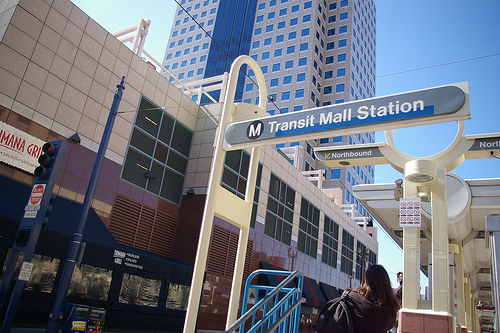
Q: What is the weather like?
A: It is clear.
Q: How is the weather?
A: It is clear.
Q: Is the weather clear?
A: Yes, it is clear.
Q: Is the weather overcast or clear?
A: It is clear.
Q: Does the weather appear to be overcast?
A: No, it is clear.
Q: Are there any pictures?
A: No, there are no pictures.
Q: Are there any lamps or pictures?
A: No, there are no pictures or lamps.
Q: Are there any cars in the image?
A: No, there are no cars.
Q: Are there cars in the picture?
A: No, there are no cars.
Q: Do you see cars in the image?
A: No, there are no cars.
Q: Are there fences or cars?
A: No, there are no cars or fences.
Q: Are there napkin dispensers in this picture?
A: No, there are no napkin dispensers.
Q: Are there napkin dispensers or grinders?
A: No, there are no napkin dispensers or grinders.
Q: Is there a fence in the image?
A: No, there are no fences.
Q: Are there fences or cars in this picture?
A: No, there are no fences or cars.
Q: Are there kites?
A: No, there are no kites.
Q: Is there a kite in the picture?
A: No, there are no kites.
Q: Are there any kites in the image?
A: No, there are no kites.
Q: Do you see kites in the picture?
A: No, there are no kites.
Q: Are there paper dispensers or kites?
A: No, there are no kites or paper dispensers.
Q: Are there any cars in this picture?
A: No, there are no cars.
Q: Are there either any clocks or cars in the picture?
A: No, there are no cars or clocks.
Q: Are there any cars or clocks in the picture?
A: No, there are no cars or clocks.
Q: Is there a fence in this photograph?
A: No, there are no fences.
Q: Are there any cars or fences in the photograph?
A: No, there are no fences or cars.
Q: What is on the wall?
A: The sign is on the wall.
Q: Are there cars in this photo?
A: No, there are no cars.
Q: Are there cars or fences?
A: No, there are no cars or fences.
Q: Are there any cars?
A: No, there are no cars.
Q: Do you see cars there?
A: No, there are no cars.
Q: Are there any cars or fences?
A: No, there are no cars or fences.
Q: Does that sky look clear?
A: Yes, the sky is clear.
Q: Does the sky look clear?
A: Yes, the sky is clear.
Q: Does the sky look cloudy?
A: No, the sky is clear.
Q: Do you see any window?
A: Yes, there is a window.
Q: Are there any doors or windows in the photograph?
A: Yes, there is a window.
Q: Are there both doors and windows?
A: No, there is a window but no doors.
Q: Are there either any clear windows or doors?
A: Yes, there is a clear window.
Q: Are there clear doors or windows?
A: Yes, there is a clear window.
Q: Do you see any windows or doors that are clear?
A: Yes, the window is clear.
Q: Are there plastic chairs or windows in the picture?
A: Yes, there is a plastic window.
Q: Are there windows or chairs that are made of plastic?
A: Yes, the window is made of plastic.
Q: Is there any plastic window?
A: Yes, there is a window that is made of plastic.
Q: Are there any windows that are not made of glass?
A: Yes, there is a window that is made of plastic.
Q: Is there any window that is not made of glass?
A: Yes, there is a window that is made of plastic.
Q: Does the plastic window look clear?
A: Yes, the window is clear.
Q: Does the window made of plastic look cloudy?
A: No, the window is clear.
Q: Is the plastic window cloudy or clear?
A: The window is clear.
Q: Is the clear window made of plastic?
A: Yes, the window is made of plastic.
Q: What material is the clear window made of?
A: The window is made of plastic.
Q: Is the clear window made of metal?
A: No, the window is made of plastic.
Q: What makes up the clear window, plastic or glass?
A: The window is made of plastic.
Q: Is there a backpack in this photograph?
A: Yes, there is a backpack.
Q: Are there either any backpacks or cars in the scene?
A: Yes, there is a backpack.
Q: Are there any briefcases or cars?
A: No, there are no cars or briefcases.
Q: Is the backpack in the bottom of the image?
A: Yes, the backpack is in the bottom of the image.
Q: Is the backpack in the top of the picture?
A: No, the backpack is in the bottom of the image.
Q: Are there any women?
A: Yes, there is a woman.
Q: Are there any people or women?
A: Yes, there is a woman.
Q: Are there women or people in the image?
A: Yes, there is a woman.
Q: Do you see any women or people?
A: Yes, there is a woman.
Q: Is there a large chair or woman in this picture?
A: Yes, there is a large woman.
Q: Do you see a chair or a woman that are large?
A: Yes, the woman is large.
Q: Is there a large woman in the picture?
A: Yes, there is a large woman.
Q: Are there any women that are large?
A: Yes, there is a woman that is large.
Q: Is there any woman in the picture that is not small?
A: Yes, there is a large woman.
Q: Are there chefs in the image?
A: No, there are no chefs.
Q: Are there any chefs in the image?
A: No, there are no chefs.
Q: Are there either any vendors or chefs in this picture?
A: No, there are no chefs or vendors.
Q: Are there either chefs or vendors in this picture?
A: No, there are no chefs or vendors.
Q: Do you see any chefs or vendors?
A: No, there are no chefs or vendors.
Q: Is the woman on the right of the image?
A: Yes, the woman is on the right of the image.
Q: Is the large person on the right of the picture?
A: Yes, the woman is on the right of the image.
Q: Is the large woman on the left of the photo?
A: No, the woman is on the right of the image.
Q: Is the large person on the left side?
A: No, the woman is on the right of the image.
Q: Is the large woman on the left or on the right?
A: The woman is on the right of the image.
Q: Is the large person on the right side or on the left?
A: The woman is on the right of the image.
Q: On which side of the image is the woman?
A: The woman is on the right of the image.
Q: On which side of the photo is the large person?
A: The woman is on the right of the image.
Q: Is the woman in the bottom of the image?
A: Yes, the woman is in the bottom of the image.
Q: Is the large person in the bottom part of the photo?
A: Yes, the woman is in the bottom of the image.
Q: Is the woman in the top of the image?
A: No, the woman is in the bottom of the image.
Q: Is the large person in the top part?
A: No, the woman is in the bottom of the image.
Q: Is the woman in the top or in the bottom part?
A: The woman is in the bottom of the image.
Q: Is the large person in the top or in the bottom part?
A: The woman is in the bottom of the image.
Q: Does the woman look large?
A: Yes, the woman is large.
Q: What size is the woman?
A: The woman is large.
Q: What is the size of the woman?
A: The woman is large.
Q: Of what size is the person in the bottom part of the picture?
A: The woman is large.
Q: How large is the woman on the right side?
A: The woman is large.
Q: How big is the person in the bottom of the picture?
A: The woman is large.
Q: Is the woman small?
A: No, the woman is large.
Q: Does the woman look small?
A: No, the woman is large.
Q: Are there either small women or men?
A: No, there is a woman but she is large.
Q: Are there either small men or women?
A: No, there is a woman but she is large.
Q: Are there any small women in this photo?
A: No, there is a woman but she is large.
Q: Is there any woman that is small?
A: No, there is a woman but she is large.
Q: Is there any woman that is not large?
A: No, there is a woman but she is large.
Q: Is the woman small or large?
A: The woman is large.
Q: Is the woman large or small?
A: The woman is large.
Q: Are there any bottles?
A: No, there are no bottles.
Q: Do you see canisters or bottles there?
A: No, there are no bottles or canisters.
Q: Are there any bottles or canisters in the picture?
A: No, there are no bottles or canisters.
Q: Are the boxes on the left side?
A: Yes, the boxes are on the left of the image.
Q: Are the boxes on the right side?
A: No, the boxes are on the left of the image.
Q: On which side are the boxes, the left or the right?
A: The boxes are on the left of the image.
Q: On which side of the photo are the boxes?
A: The boxes are on the left of the image.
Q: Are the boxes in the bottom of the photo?
A: Yes, the boxes are in the bottom of the image.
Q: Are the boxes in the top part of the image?
A: No, the boxes are in the bottom of the image.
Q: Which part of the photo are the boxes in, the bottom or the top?
A: The boxes are in the bottom of the image.